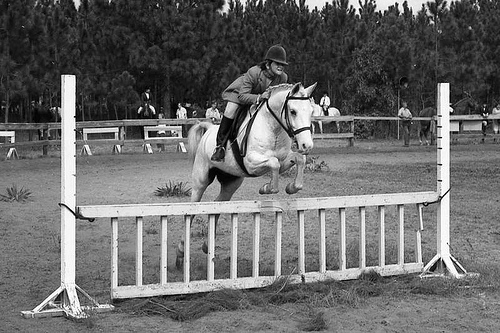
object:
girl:
[210, 44, 287, 163]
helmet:
[261, 44, 290, 67]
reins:
[237, 89, 312, 160]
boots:
[208, 114, 235, 159]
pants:
[222, 100, 238, 120]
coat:
[221, 65, 289, 106]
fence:
[76, 191, 287, 301]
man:
[396, 100, 412, 148]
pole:
[434, 80, 451, 254]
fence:
[1, 113, 499, 159]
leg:
[243, 147, 280, 192]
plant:
[154, 179, 193, 200]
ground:
[0, 134, 499, 332]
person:
[134, 85, 156, 116]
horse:
[137, 102, 165, 153]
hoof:
[258, 184, 269, 195]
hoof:
[287, 182, 294, 196]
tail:
[185, 119, 213, 165]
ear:
[305, 83, 319, 99]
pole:
[53, 72, 79, 288]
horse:
[175, 80, 314, 268]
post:
[23, 74, 113, 320]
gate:
[18, 74, 479, 320]